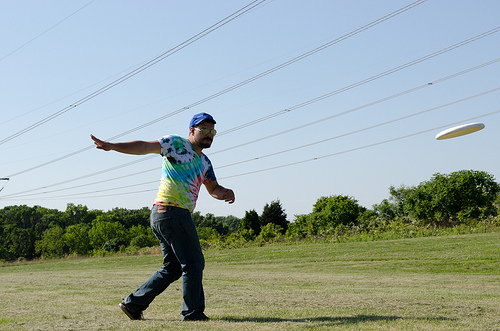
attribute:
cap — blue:
[191, 112, 212, 131]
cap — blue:
[187, 110, 217, 127]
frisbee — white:
[430, 116, 489, 145]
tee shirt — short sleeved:
[153, 135, 216, 205]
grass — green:
[1, 219, 494, 329]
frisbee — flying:
[396, 98, 493, 147]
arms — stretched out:
[95, 129, 235, 199]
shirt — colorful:
[153, 136, 216, 208]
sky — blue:
[0, 3, 500, 175]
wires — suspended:
[117, 14, 483, 148]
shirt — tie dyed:
[155, 133, 215, 214]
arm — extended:
[89, 135, 158, 155]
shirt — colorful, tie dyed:
[152, 130, 211, 216]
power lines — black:
[4, 5, 497, 197]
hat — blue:
[190, 111, 215, 123]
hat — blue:
[185, 107, 231, 159]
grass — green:
[304, 231, 499, 288]